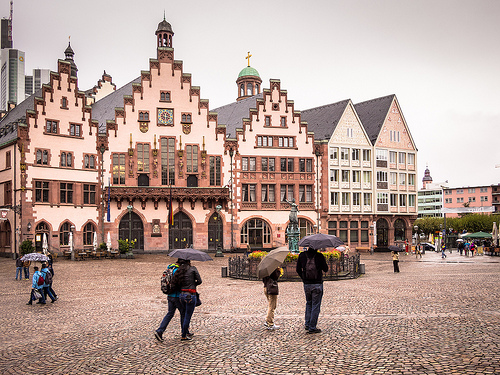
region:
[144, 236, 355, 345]
people on a street with umbrellas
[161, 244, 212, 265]
top of black umbrella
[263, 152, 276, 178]
window on a building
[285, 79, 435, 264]
buildings along side of street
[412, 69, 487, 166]
cloudy sky in the distance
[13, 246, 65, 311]
people strolling through the street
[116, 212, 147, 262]
doorway to a building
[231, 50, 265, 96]
dome with a cross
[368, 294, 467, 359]
cobblestone road by buildings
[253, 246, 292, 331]
a person holding an umbrella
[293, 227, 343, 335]
a person holding an umbrella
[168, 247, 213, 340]
a person holding an umbrella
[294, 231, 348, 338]
a person holding a black umbrella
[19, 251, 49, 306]
a person holding an umbrella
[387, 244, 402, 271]
a person holding an umbrella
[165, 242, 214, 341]
a person holding a black umbrella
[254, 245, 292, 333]
a person holding a brown umbrella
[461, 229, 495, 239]
a green tent in the distance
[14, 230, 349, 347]
People are holding umbrellas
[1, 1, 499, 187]
The sky appears overcast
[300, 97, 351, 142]
A roof on a building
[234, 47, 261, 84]
A cross on top of a tower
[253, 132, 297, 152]
Windows on a building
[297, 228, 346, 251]
A black and open umbrella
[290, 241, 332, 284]
Person is carrying a backpack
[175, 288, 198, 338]
A pair of blue jeans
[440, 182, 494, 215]
A building is pink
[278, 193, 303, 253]
A statue is displayed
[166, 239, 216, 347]
a woman carrying an umbrella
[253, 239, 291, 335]
a woman carrying an umbrella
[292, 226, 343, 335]
a man carrying an umbrella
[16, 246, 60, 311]
a couple carrying an umbrella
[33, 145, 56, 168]
the windows of a building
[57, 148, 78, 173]
the windows of a building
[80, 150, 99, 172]
the windows of a building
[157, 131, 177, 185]
the windows of a building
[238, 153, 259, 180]
the windows of a building